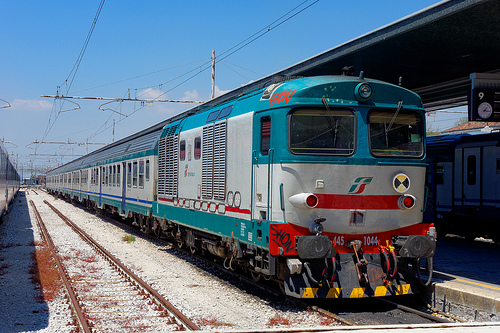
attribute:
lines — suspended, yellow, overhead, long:
[66, 45, 132, 124]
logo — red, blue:
[345, 171, 376, 206]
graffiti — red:
[268, 226, 302, 261]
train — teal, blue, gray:
[245, 93, 445, 262]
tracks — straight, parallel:
[38, 255, 153, 332]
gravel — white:
[46, 208, 72, 234]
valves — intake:
[382, 175, 413, 194]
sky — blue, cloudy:
[216, 26, 227, 29]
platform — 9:
[467, 266, 498, 321]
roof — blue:
[251, 72, 292, 123]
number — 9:
[474, 84, 491, 98]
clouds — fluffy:
[9, 90, 35, 119]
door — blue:
[118, 160, 130, 226]